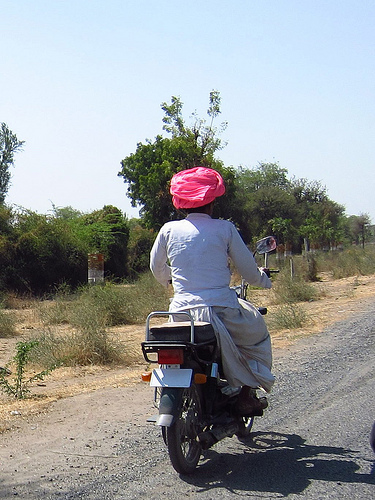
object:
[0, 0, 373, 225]
clouds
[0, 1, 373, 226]
sky